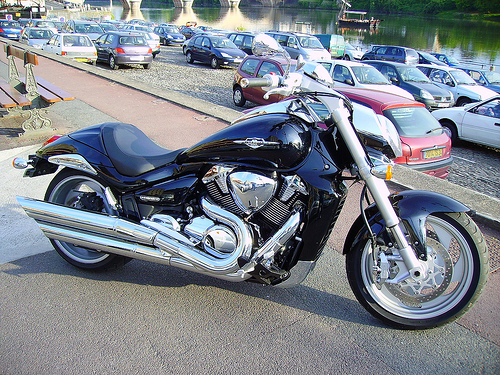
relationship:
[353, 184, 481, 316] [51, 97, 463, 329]
tire of bike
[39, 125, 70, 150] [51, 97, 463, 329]
signal of bike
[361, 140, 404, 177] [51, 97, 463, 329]
signal of bike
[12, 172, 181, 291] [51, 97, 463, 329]
exhaust of bike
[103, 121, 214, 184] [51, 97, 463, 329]
seat of bike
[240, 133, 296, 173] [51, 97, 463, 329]
emblem of bike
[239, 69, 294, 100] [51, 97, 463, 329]
handlebar of bike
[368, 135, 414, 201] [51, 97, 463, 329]
headlight of bike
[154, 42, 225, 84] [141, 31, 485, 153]
gravel of lot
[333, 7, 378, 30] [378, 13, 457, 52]
boat i water